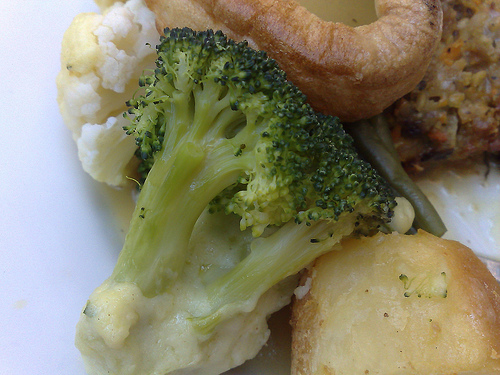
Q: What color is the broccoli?
A: Green.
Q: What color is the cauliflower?
A: Off white.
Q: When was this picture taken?
A: After cooking.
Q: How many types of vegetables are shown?
A: Two.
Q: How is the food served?
A: On a plate.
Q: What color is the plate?
A: White.